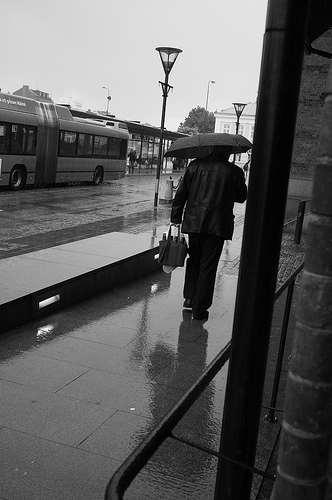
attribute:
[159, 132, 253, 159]
umbrella — black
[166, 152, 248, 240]
jacket — dark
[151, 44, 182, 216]
pole — black